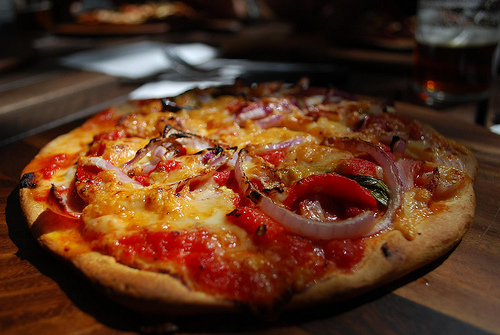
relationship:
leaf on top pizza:
[352, 174, 392, 206] [14, 64, 478, 315]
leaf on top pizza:
[352, 174, 392, 206] [81, 55, 421, 263]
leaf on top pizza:
[358, 165, 393, 208] [14, 64, 478, 315]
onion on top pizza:
[237, 132, 404, 236] [108, 103, 383, 278]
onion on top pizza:
[237, 132, 404, 236] [14, 64, 478, 315]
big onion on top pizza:
[131, 111, 364, 253] [20, 77, 478, 315]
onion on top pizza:
[237, 132, 404, 236] [30, 37, 465, 301]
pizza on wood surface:
[20, 77, 478, 315] [1, 254, 498, 331]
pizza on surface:
[14, 64, 478, 315] [1, 58, 497, 328]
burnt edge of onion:
[134, 121, 216, 150] [85, 124, 237, 192]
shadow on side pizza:
[6, 183, 145, 325] [31, 84, 471, 286]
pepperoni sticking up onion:
[228, 156, 396, 246] [237, 132, 404, 236]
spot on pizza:
[19, 170, 44, 190] [23, 51, 482, 332]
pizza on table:
[20, 77, 478, 315] [1, 73, 498, 332]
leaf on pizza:
[352, 174, 392, 206] [20, 77, 478, 315]